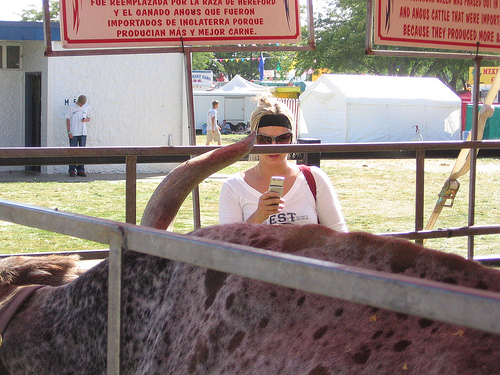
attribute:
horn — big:
[133, 130, 263, 249]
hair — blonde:
[244, 90, 297, 167]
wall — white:
[1, 37, 188, 171]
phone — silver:
[264, 172, 288, 213]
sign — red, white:
[56, 0, 305, 46]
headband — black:
[253, 111, 293, 131]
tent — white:
[292, 74, 462, 152]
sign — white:
[54, 1, 302, 43]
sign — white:
[51, 0, 299, 50]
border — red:
[64, 31, 311, 41]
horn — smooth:
[132, 126, 267, 241]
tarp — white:
[288, 70, 468, 150]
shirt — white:
[64, 100, 94, 138]